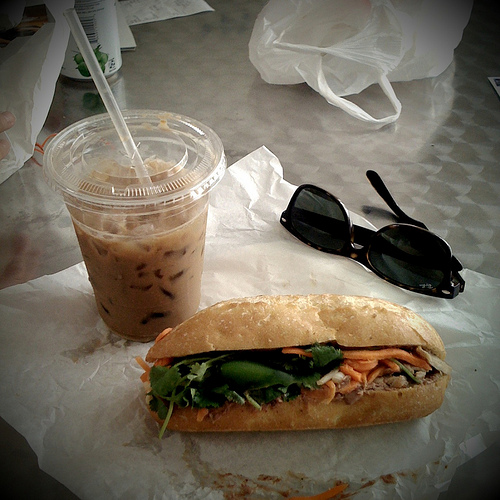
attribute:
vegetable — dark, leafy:
[141, 333, 309, 411]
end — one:
[125, 282, 281, 424]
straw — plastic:
[59, 56, 146, 133]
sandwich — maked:
[133, 292, 451, 439]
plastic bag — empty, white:
[247, 4, 475, 125]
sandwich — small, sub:
[129, 307, 469, 462]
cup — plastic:
[25, 52, 232, 361]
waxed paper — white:
[0, 144, 499, 499]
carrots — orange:
[146, 312, 471, 424]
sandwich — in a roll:
[95, 264, 485, 440]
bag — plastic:
[244, 3, 484, 147]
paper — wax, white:
[4, 147, 491, 493]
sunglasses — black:
[280, 168, 467, 300]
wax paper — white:
[2, 147, 496, 499]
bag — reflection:
[250, 0, 479, 127]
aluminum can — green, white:
[44, 0, 121, 80]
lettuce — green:
[150, 339, 343, 409]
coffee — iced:
[63, 145, 217, 346]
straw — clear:
[111, 118, 139, 165]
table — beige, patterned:
[8, 4, 498, 487]